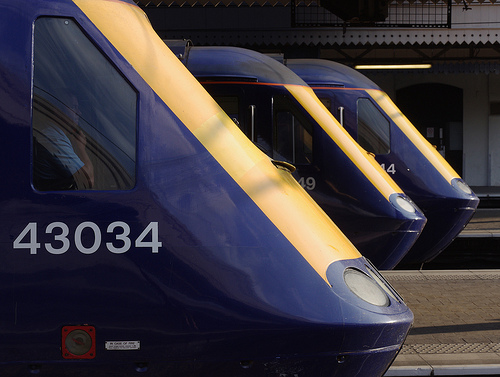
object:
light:
[354, 63, 431, 69]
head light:
[343, 264, 392, 306]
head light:
[396, 195, 416, 214]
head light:
[451, 177, 474, 196]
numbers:
[298, 176, 315, 192]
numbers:
[379, 162, 397, 175]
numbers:
[12, 222, 163, 256]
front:
[167, 38, 429, 270]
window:
[30, 16, 137, 194]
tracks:
[356, 190, 498, 375]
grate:
[292, 0, 499, 46]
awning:
[313, 50, 499, 69]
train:
[0, 1, 412, 376]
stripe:
[310, 87, 367, 89]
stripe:
[196, 82, 283, 86]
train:
[260, 53, 480, 269]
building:
[141, 0, 499, 209]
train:
[158, 37, 428, 271]